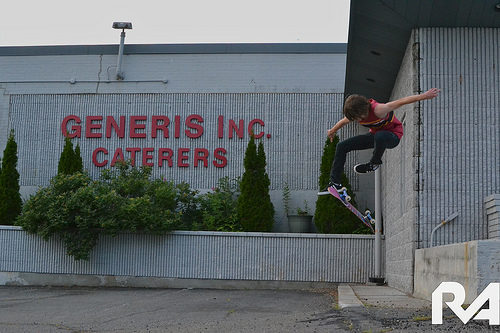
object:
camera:
[111, 21, 133, 31]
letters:
[63, 110, 275, 171]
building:
[1, 50, 499, 280]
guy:
[315, 86, 434, 195]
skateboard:
[326, 187, 376, 229]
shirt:
[361, 98, 405, 139]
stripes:
[358, 111, 395, 127]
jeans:
[329, 132, 398, 181]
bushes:
[26, 170, 189, 261]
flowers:
[45, 186, 158, 202]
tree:
[307, 133, 356, 233]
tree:
[238, 137, 275, 230]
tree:
[58, 139, 85, 174]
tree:
[3, 131, 25, 220]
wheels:
[362, 206, 376, 223]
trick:
[320, 76, 432, 229]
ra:
[431, 282, 498, 325]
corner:
[460, 239, 499, 332]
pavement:
[5, 278, 355, 332]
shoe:
[354, 161, 379, 175]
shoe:
[316, 179, 347, 195]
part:
[329, 186, 343, 199]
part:
[350, 307, 485, 331]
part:
[340, 191, 348, 199]